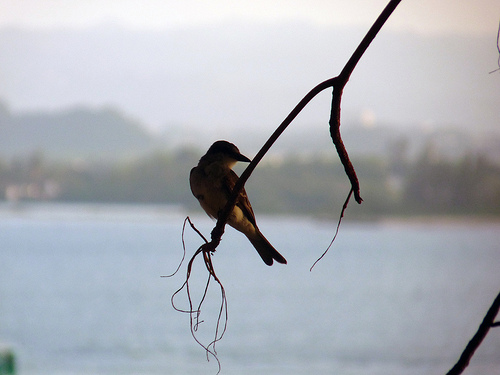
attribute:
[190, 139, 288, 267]
bird — brown, small, looking, looking right, outdoors, lovely, pretty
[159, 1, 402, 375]
branch — medium, leafless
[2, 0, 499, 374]
background — blurry, hilly, shoreline, tan, skyline, mountains, shadowy, trees, hazy, hills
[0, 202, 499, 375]
water — blue, lake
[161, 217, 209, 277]
twig — small, stringy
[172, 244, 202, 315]
twig — small, stringy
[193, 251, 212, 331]
twig — small, stringy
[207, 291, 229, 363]
twig — small, stringy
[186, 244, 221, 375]
twig — small, stringy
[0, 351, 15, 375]
object — green, blurry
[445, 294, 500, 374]
branch — medium, leafless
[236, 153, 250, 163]
beak — sharp